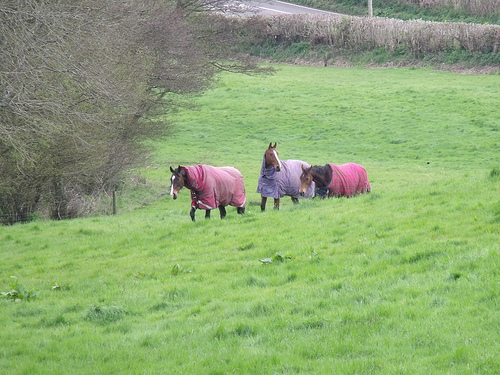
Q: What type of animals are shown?
A: Horses.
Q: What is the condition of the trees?
A: Bare.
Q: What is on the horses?
A: Blankets.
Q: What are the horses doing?
A: Walking.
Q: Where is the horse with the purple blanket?
A: In the middle.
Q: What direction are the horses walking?
A: Left.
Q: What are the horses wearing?
A: Blankets.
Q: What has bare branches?
A: The trees.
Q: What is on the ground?
A: Grass.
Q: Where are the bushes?
A: On the edge of the field.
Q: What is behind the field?
A: A road.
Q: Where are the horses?
A: In a field.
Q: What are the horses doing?
A: Walking in the field.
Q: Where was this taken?
A: In a field.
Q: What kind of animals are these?
A: Horses.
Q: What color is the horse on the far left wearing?
A: Pink.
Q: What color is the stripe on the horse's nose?
A: White.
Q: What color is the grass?
A: Green.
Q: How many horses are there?
A: 3.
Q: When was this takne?
A: Daytime.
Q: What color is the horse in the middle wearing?
A: Purple.